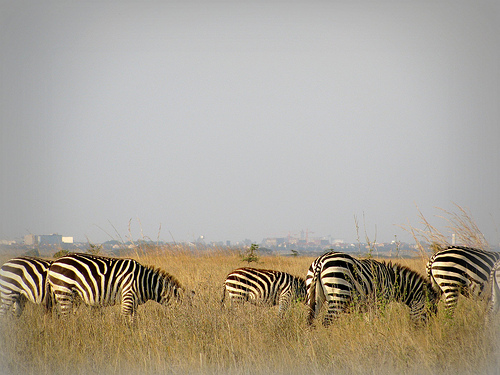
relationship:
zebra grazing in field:
[40, 252, 196, 319] [1, 250, 498, 374]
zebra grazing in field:
[221, 264, 306, 310] [1, 250, 498, 374]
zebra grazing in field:
[303, 248, 436, 337] [1, 250, 498, 374]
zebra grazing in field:
[420, 245, 499, 319] [1, 250, 498, 374]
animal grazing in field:
[0, 255, 55, 318] [1, 250, 498, 374]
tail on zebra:
[304, 262, 322, 328] [37, 223, 209, 360]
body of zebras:
[305, 253, 393, 327] [299, 245, 496, 331]